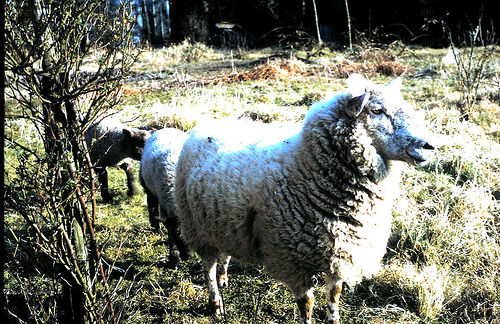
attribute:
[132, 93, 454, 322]
sheep — white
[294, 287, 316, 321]
leg — white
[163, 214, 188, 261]
leg — black 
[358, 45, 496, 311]
grass — overgrown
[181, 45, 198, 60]
white sheep — standing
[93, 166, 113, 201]
leg — black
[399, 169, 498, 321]
grass — green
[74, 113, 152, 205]
lamb — small, black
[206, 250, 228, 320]
legs — thin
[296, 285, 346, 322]
legs — thin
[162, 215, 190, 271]
leg — black 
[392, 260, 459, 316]
grass — green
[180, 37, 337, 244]
sheep — standing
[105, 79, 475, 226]
sheep — White 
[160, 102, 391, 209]
sheep — black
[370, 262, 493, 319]
grass — green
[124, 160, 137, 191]
leg — black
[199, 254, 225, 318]
leg — white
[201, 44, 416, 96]
moss — brown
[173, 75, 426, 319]
sheep — several, white, wooly, standing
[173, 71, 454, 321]
sheep — white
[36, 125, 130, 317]
branches — leafless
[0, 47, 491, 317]
grass — green